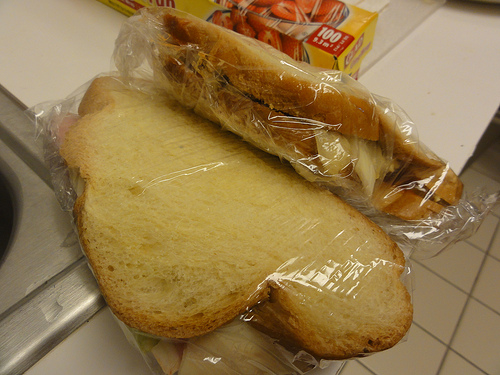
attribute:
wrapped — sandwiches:
[58, 6, 467, 372]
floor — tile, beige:
[418, 258, 500, 359]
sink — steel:
[8, 156, 73, 336]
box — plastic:
[262, 4, 383, 68]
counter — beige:
[408, 40, 492, 122]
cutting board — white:
[383, 13, 414, 42]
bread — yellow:
[79, 78, 250, 320]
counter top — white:
[14, 10, 99, 74]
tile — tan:
[419, 263, 484, 363]